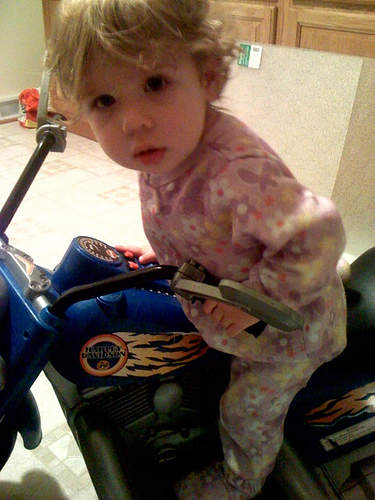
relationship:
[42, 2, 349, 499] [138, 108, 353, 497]
baby wearing jammies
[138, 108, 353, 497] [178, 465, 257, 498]
jammies have feet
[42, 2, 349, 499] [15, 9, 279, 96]
baby has hair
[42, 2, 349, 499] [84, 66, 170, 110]
baby has eyes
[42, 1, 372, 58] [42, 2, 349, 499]
cabinet behind baby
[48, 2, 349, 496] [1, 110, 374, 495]
baby on motorcycle